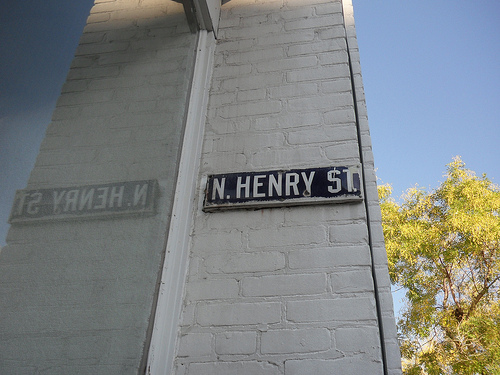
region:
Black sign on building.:
[202, 160, 362, 204]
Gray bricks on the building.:
[160, 0, 380, 370]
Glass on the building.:
[1, 0, 200, 373]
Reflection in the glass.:
[7, 179, 159, 229]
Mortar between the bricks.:
[174, 350, 344, 361]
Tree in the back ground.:
[370, 153, 498, 370]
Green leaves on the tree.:
[376, 178, 498, 370]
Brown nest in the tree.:
[451, 302, 463, 322]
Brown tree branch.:
[443, 268, 457, 303]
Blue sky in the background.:
[355, 1, 495, 189]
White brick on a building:
[197, 301, 290, 322]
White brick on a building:
[253, 324, 338, 361]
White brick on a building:
[277, 290, 379, 328]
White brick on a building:
[240, 219, 328, 250]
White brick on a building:
[214, 129, 297, 150]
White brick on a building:
[281, 118, 361, 145]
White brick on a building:
[245, 142, 321, 167]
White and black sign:
[200, 170, 365, 211]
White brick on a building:
[242, 26, 311, 49]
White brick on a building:
[243, 80, 323, 129]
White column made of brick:
[173, 5, 404, 368]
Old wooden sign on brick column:
[201, 165, 367, 212]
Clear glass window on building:
[5, 5, 210, 372]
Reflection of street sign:
[13, 172, 157, 228]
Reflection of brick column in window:
[0, 2, 204, 370]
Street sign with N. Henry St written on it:
[202, 163, 364, 215]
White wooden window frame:
[135, 0, 230, 368]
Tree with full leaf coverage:
[374, 155, 499, 371]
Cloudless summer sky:
[351, 3, 494, 188]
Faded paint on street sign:
[202, 193, 367, 209]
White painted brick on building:
[178, 329, 238, 368]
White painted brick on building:
[228, 324, 293, 362]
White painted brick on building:
[298, 321, 373, 373]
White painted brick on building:
[309, 277, 379, 324]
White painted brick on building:
[254, 266, 311, 313]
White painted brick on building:
[191, 271, 255, 331]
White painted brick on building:
[203, 222, 273, 267]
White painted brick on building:
[265, 215, 330, 252]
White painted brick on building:
[284, 119, 380, 146]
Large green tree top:
[370, 156, 497, 273]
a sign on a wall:
[200, 145, 365, 217]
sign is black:
[197, 160, 364, 211]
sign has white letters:
[203, 163, 365, 210]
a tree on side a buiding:
[353, 145, 498, 373]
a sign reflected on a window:
[2, 152, 168, 228]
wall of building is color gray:
[192, 5, 392, 372]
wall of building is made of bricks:
[168, 0, 413, 374]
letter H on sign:
[227, 165, 252, 205]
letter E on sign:
[247, 167, 267, 202]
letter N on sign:
[264, 168, 285, 198]